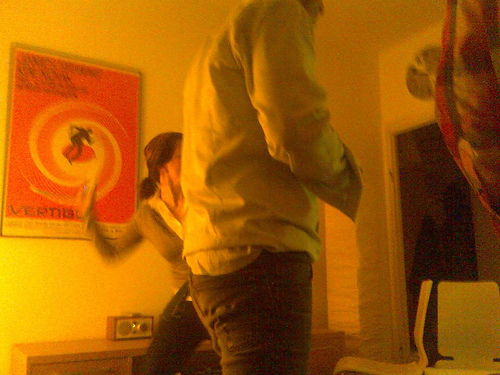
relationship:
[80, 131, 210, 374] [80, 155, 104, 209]
woman has remote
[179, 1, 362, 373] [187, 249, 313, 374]
man wearing jeans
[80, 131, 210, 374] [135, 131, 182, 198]
woman has hair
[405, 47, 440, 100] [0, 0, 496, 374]
clock on wall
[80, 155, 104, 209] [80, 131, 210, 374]
remote held by woman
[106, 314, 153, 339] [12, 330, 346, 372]
radio on cabinet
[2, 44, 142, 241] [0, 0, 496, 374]
poster on wall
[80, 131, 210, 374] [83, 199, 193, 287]
woman wearing sweater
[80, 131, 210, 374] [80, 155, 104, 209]
woman swinging remote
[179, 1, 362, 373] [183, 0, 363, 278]
man wearing shirt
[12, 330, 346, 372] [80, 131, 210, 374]
cabinet behind woman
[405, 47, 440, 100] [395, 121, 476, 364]
clock above door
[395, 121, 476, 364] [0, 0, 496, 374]
door on wall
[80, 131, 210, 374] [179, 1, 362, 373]
woman behind man